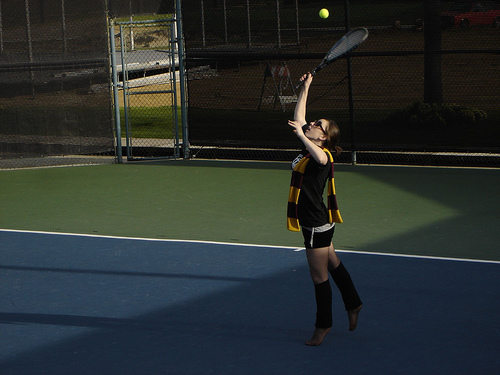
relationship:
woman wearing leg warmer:
[286, 72, 362, 347] [315, 278, 331, 329]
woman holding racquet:
[286, 72, 362, 347] [294, 25, 370, 89]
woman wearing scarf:
[286, 72, 362, 347] [285, 148, 343, 233]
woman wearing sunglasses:
[286, 72, 362, 347] [311, 117, 329, 136]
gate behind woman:
[2, 3, 300, 102] [286, 72, 362, 347]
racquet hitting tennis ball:
[294, 25, 370, 89] [317, 6, 329, 20]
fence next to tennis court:
[0, 2, 499, 173] [0, 158, 500, 374]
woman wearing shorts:
[286, 72, 362, 347] [299, 221, 335, 249]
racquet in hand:
[294, 25, 370, 89] [299, 71, 314, 86]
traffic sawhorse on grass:
[252, 58, 299, 112] [1, 103, 497, 155]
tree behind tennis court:
[382, 3, 490, 122] [0, 158, 500, 374]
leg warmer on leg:
[315, 278, 331, 329] [303, 230, 333, 347]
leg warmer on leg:
[328, 263, 362, 313] [328, 241, 363, 331]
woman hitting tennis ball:
[286, 72, 362, 347] [317, 6, 329, 20]